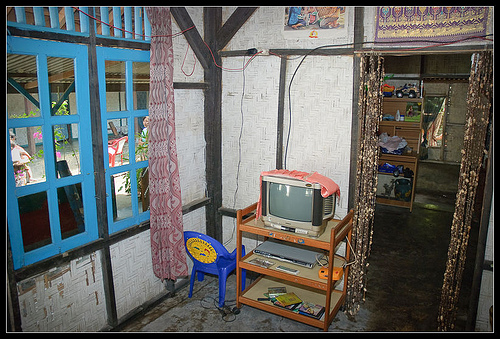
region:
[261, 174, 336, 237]
silver and black television set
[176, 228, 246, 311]
small child's purple chair with yellow design on back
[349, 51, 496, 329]
pair of gold interior curtains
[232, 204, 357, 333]
three shelf television stand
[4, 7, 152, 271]
blue framed window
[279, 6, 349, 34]
painting on wall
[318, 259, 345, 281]
orange game controller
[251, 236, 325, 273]
silver and black media player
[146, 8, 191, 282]
red and grey curtains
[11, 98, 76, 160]
green plant with pink flowers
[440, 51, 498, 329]
Macrame curtain hanging in doorway to another room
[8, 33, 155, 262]
Bright blue panted window trim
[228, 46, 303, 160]
Electrical wires hanging from wall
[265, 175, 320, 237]
Small television in room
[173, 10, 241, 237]
Wood corner wall support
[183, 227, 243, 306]
Children's plastic blue chair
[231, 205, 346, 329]
Television cart with 3 shelves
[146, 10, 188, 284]
Pink and red curtains for big window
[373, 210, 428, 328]
Bare concrete floor inside of house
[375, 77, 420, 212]
Tall wooden shelf with toys and clothes on it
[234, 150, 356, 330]
television set on stand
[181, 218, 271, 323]
blue chair with yellow picture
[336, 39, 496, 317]
gold sparkly divider in doorway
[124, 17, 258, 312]
red and white drape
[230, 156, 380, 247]
orange cloth over top of television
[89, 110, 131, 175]
red and white chair outside window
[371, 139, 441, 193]
blue stuff on shelf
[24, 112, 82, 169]
pink flowers outside window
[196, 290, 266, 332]
black wire on floor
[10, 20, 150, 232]
The window is blue.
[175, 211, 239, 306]
The chair has a yellow sun on the back of it.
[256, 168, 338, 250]
The television is very old.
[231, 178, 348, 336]
The television is sitting on tv stand.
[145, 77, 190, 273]
The curtain is red and white.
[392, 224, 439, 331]
The floor is dirty.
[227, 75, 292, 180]
Cords are hanging from the wall.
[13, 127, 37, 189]
A person is standing outside.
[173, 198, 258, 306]
The kid's chair is in the corner.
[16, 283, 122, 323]
The paint on the walls is peeling.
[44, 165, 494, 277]
picture taken indoors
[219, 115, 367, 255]
a tv is off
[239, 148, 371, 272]
the tv is on a stand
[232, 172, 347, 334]
a small chair next to the tv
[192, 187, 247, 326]
the chair is blue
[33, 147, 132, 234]
the windows are painted blue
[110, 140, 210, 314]
the window has curtains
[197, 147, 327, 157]
the walls are light tan in color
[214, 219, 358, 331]
the tv stand is made of wood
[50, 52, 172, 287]
the windows are made of wood